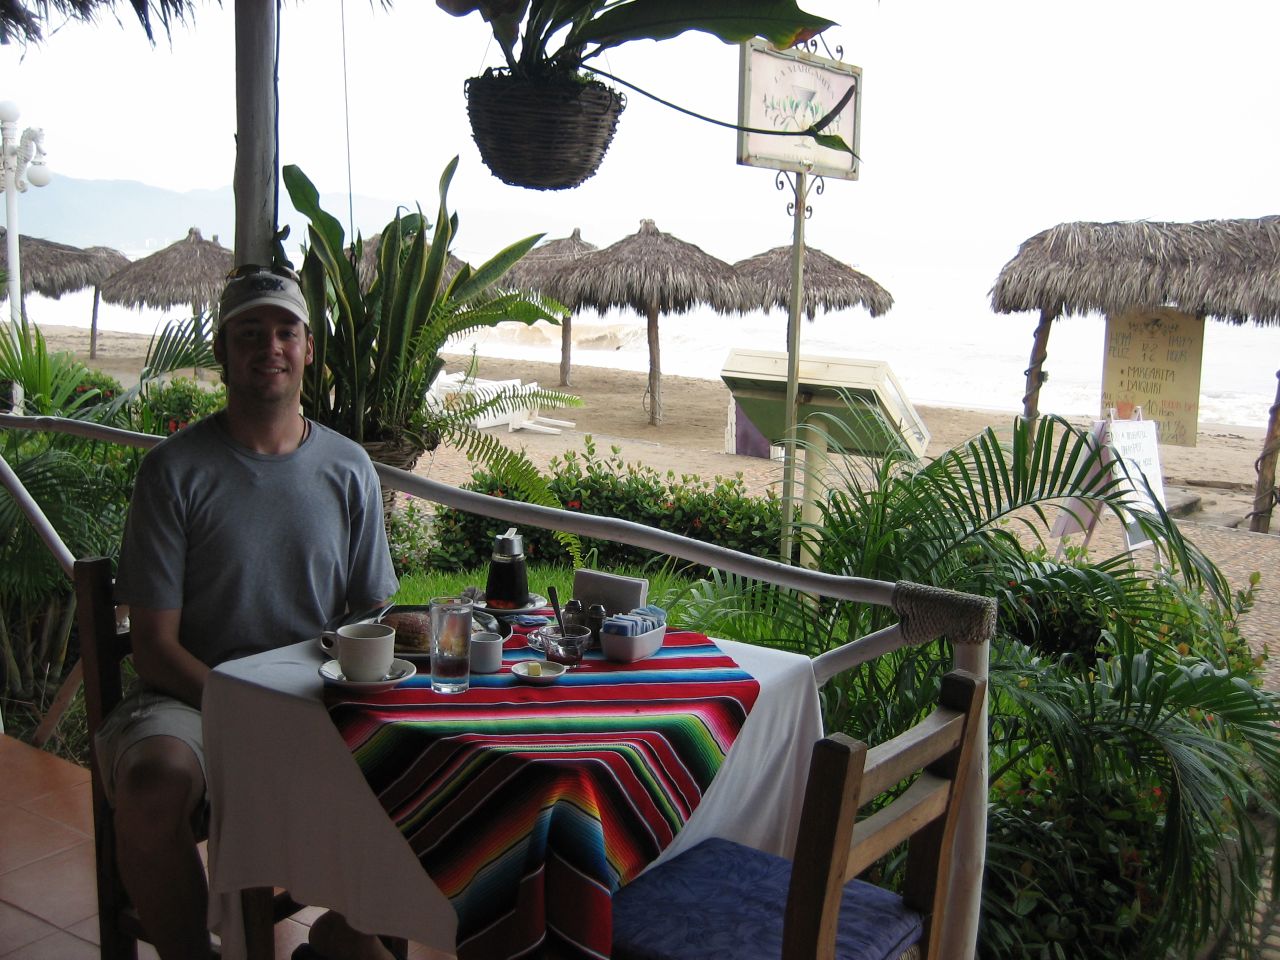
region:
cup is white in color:
[352, 609, 405, 680]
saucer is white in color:
[325, 656, 420, 694]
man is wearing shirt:
[149, 398, 384, 663]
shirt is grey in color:
[131, 422, 366, 656]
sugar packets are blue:
[595, 600, 684, 642]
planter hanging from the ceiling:
[467, 64, 637, 195]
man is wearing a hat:
[189, 247, 333, 340]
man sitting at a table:
[98, 271, 408, 956]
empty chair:
[607, 710, 978, 956]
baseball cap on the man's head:
[210, 278, 310, 332]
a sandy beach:
[23, 322, 1277, 689]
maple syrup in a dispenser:
[486, 521, 529, 608]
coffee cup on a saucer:
[316, 622, 411, 691]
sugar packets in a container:
[605, 605, 663, 659]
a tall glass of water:
[431, 604, 473, 695]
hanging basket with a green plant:
[433, 0, 833, 197]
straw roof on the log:
[573, 207, 704, 322]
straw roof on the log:
[94, 221, 262, 361]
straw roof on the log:
[979, 190, 1277, 345]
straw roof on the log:
[68, 223, 135, 365]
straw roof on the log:
[2, 218, 102, 338]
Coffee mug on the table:
[302, 609, 413, 705]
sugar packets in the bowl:
[602, 591, 666, 658]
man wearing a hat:
[203, 249, 331, 331]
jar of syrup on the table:
[481, 510, 537, 601]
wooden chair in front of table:
[655, 688, 1013, 958]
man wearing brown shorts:
[59, 657, 240, 819]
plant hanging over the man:
[452, 2, 654, 172]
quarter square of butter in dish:
[505, 641, 576, 688]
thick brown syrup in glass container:
[486, 522, 533, 611]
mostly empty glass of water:
[422, 586, 473, 701]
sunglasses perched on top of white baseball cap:
[214, 248, 312, 326]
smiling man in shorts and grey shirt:
[95, 248, 396, 957]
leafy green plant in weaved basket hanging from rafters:
[397, 4, 845, 194]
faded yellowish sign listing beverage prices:
[1103, 306, 1207, 448]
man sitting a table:
[96, 258, 408, 958]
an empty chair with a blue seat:
[601, 657, 995, 958]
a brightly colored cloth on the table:
[314, 574, 765, 958]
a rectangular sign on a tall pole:
[722, 26, 870, 570]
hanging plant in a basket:
[416, 0, 832, 193]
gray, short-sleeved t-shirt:
[118, 412, 406, 706]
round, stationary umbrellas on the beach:
[0, 196, 906, 444]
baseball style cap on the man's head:
[206, 263, 312, 339]